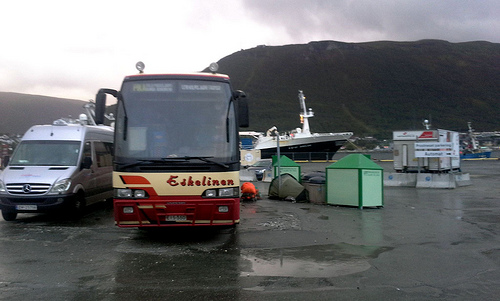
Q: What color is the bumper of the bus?
A: Red.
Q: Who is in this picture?
A: No one.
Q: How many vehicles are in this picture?
A: Two.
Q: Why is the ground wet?
A: Rain.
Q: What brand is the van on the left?
A: Mercedes.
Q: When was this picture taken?
A: Daytime.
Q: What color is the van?
A: Silver.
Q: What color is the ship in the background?
A: Black and white.